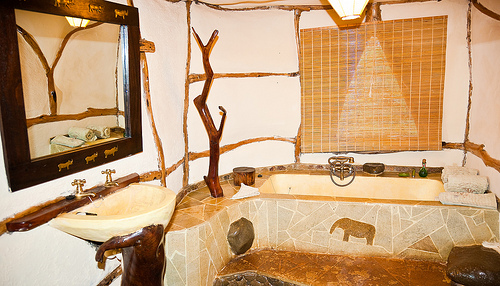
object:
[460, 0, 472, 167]
crack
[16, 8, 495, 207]
wall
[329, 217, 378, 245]
elephant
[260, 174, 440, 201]
bath tub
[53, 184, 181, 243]
sink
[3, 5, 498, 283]
bathroom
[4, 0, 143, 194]
mirror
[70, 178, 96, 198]
faucet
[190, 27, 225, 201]
tree branch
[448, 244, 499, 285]
sitting area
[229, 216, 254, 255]
rock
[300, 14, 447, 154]
bamboo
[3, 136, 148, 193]
wooden frame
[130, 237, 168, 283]
wood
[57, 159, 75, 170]
animals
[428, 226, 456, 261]
tile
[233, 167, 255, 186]
wooden box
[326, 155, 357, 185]
faucet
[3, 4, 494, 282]
picture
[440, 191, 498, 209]
towels